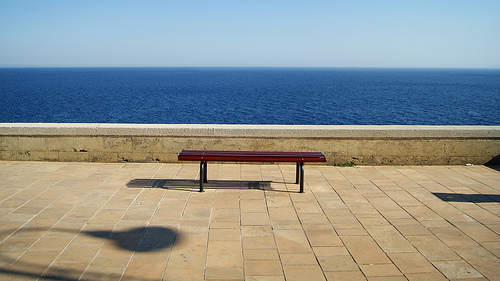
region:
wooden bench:
[173, 136, 327, 191]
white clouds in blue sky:
[24, 23, 48, 61]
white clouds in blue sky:
[36, 16, 94, 57]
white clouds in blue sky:
[140, 10, 168, 50]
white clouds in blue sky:
[81, 20, 125, 54]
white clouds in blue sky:
[230, 11, 275, 66]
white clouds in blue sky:
[304, 3, 328, 51]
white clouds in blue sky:
[357, 19, 384, 50]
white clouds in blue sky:
[431, 0, 461, 50]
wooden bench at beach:
[184, 138, 338, 195]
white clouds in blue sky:
[115, 8, 159, 66]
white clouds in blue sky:
[190, 11, 204, 33]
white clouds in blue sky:
[246, 15, 273, 50]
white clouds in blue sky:
[320, 17, 356, 70]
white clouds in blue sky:
[398, 19, 422, 48]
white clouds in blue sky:
[263, 8, 299, 37]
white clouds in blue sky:
[148, 12, 186, 45]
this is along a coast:
[21, 20, 448, 248]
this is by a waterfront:
[5, 55, 432, 276]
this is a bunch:
[170, 140, 350, 208]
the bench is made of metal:
[175, 135, 333, 167]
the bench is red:
[165, 130, 378, 190]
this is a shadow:
[36, 185, 182, 253]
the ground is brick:
[171, 200, 401, 276]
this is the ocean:
[83, 56, 378, 176]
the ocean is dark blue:
[167, 60, 417, 147]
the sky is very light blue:
[188, 14, 395, 70]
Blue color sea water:
[116, 78, 371, 103]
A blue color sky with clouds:
[138, 17, 365, 39]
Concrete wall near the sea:
[31, 123, 433, 140]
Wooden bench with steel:
[179, 146, 325, 194]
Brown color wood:
[175, 144, 326, 163]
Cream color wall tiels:
[358, 189, 465, 249]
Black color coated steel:
[196, 172, 313, 190]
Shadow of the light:
[26, 219, 189, 257]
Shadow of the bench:
[130, 164, 287, 216]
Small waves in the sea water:
[231, 70, 403, 100]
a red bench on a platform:
[176, 144, 331, 196]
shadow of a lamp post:
[9, 207, 187, 264]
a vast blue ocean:
[6, 57, 497, 125]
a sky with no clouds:
[4, 8, 499, 65]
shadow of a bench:
[126, 173, 282, 194]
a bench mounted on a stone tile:
[172, 143, 327, 195]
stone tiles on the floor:
[199, 193, 404, 279]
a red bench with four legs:
[169, 143, 338, 195]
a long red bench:
[170, 139, 331, 195]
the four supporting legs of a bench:
[195, 161, 305, 193]